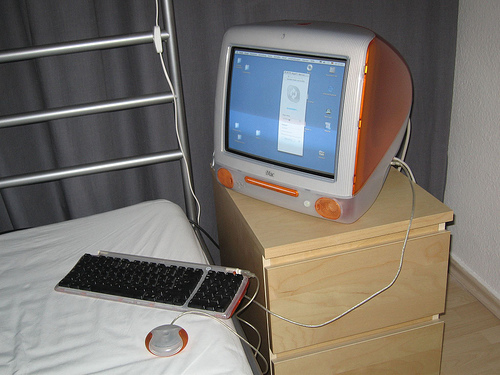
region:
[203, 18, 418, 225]
A grey and orange computer monitor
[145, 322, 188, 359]
A grey and orange mouse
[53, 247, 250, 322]
The keyboard for the computer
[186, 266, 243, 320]
The number pad on the keyboard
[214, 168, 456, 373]
A wooden bedside desk of drawers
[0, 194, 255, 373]
A white mattress on the bed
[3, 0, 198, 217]
The iron frame of a headboard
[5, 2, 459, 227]
Grey curtains behind the bed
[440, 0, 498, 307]
A white wall with a tan baseboard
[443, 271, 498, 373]
Wooden floor of the room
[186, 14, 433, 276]
a orange and white computer screen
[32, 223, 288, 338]
a orange and white keyboard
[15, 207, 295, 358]
a orange and white keyboard on a bed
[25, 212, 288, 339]
a keyboard on a bed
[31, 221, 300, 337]
black keys on a keyboard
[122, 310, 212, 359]
a white and orange mouse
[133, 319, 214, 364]
a white and orange computer mouse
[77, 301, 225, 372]
a computer mouse on a bed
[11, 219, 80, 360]
white sheets on a bed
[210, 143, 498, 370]
a brown wooden end table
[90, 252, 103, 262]
black key on keyboard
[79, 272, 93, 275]
black key on keyboard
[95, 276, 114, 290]
black key on keyboard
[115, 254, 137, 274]
black key on keyboard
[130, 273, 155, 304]
black key on keyboard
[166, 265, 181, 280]
black key on keyboard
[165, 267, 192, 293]
black key on keyboard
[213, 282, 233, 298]
black key on keyboard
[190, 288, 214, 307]
black key on keyboard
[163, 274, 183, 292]
black key on keyboard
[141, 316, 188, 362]
orange and clear mouse for a mac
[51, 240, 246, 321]
keyboard with black keys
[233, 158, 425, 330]
cord going from the computer to the keyboard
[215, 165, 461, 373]
a wooden dresser on the side of the bed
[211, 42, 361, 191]
blue computer screen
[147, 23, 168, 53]
button on the computer cord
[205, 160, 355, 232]
two orange speakers on the mac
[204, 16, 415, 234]
a mac computer on a dresser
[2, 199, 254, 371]
side corner of a white bed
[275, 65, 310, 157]
an opened program on the computer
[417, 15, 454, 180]
the curtain is gray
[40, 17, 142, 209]
the curtain is gray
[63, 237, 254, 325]
keyboard on the bed